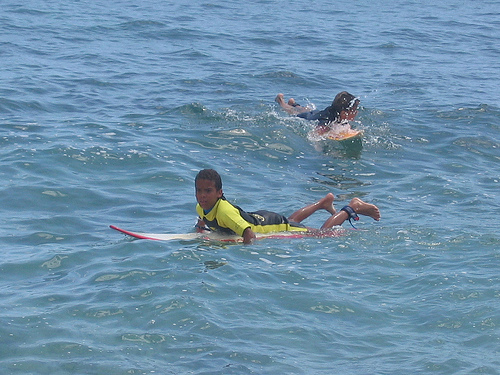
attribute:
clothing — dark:
[284, 105, 338, 127]